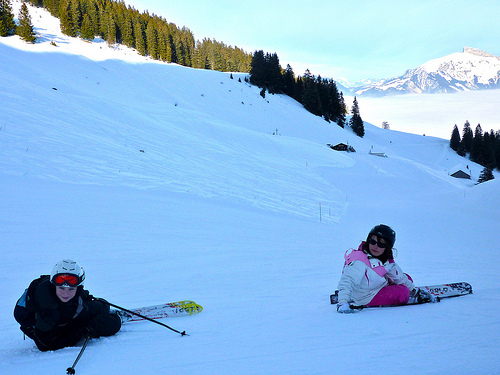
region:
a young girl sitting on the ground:
[328, 217, 450, 328]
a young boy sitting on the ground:
[5, 270, 223, 360]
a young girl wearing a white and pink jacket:
[331, 223, 411, 323]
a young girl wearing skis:
[331, 226, 476, 337]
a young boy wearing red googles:
[27, 255, 115, 317]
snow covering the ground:
[20, 107, 300, 222]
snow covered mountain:
[371, 40, 482, 117]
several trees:
[69, 15, 284, 72]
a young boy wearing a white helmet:
[39, 246, 88, 316]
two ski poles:
[76, 261, 189, 373]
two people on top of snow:
[16, 207, 476, 350]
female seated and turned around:
[316, 202, 471, 327]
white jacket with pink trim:
[330, 215, 432, 330]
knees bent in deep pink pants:
[327, 213, 451, 328]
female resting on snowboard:
[301, 205, 471, 315]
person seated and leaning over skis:
[15, 250, 215, 360]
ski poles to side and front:
[10, 250, 195, 370]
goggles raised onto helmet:
[11, 242, 197, 352]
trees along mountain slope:
[80, 5, 361, 145]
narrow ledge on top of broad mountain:
[388, 31, 493, 96]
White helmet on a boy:
[47, 256, 91, 291]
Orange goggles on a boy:
[42, 266, 93, 288]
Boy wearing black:
[11, 252, 138, 346]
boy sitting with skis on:
[19, 241, 224, 360]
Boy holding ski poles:
[25, 255, 175, 368]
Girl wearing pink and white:
[337, 202, 476, 327]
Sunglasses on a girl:
[347, 219, 412, 281]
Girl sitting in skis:
[333, 206, 476, 313]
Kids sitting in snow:
[25, 185, 477, 374]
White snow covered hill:
[105, 146, 330, 282]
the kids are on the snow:
[11, 224, 469, 372]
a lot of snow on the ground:
[0, 0, 498, 367]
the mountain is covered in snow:
[345, 40, 495, 95]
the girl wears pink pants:
[365, 285, 406, 307]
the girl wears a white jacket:
[340, 252, 415, 308]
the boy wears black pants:
[28, 308, 120, 351]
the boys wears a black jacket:
[16, 275, 92, 330]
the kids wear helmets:
[47, 225, 396, 289]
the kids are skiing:
[12, 224, 470, 371]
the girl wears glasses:
[369, 240, 390, 250]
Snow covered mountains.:
[350, 45, 499, 97]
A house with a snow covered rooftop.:
[443, 162, 475, 180]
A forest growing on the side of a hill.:
[51, 0, 257, 69]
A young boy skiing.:
[9, 253, 219, 350]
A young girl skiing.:
[327, 219, 487, 317]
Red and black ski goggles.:
[48, 270, 87, 287]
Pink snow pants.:
[367, 277, 417, 310]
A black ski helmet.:
[368, 222, 397, 241]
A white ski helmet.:
[51, 259, 83, 275]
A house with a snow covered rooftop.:
[320, 135, 358, 155]